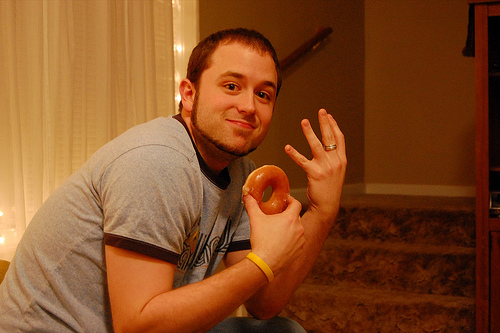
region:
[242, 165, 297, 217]
doughnut in man's hand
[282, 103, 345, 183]
fingers held up by man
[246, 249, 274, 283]
band around man's wrist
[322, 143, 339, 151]
ring of man on finger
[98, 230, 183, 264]
black strip on shirt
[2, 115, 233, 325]
grey shirt on man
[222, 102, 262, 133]
smile on face of man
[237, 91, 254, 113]
nose of man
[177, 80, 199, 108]
ear of man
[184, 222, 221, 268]
writing on man's shirt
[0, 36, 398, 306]
man holding a donut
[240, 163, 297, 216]
donut in person's hand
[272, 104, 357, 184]
hand of a person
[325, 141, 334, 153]
ring on person's hand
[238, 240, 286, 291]
yellow bracelet on hand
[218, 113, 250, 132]
mouth of the boy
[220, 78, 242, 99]
eye of the man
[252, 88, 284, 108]
eye of the man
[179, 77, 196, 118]
ear of the man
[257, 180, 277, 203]
hole in the middle of the donut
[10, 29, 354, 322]
man holding four fingers up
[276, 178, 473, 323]
staircase behind man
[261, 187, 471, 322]
staircase with three stairs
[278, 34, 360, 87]
railing on the wall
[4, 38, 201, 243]
white curtain covering the window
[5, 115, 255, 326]
gray ringer tshirt of man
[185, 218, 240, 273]
design on gray shirt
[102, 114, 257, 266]
black rings on neck and sleeves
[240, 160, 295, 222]
doughnut man is holding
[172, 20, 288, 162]
The man has hair.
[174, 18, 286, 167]
The man's hair is short.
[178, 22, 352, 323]
The man is wearing a ring.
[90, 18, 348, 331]
The man is holding a donut.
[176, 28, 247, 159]
The man has a ear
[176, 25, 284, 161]
The man has two eyes.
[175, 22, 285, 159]
The man's eyes are open.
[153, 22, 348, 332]
Man has a yellow band around his wrist.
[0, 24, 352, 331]
The man is wearing a shirt.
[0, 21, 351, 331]
The man's shirt has sleeves.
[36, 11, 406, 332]
Man with a donut.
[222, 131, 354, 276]
Doughnut in the man's hand.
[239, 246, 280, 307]
Bracelet on the man's wrist.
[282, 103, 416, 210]
ring on the man's finger.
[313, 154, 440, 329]
Stairs in the background.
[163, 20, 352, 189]
Man with a beard.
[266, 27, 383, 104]
Rail on the wall.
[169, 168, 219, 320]
Logo on the shirt.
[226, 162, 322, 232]
Iced doughnut in the man's hand.